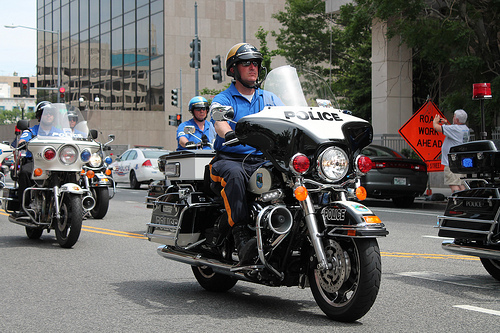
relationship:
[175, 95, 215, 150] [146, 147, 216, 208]
policeman riding motorcycle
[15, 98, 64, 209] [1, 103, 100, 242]
policeman riding motorcycle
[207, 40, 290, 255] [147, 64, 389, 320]
policeman riding motorcycle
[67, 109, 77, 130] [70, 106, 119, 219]
policeman riding motorcycle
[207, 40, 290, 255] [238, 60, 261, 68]
policeman wearing sunglasses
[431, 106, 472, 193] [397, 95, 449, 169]
man working on sign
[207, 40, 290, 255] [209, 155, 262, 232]
policeman wearing pants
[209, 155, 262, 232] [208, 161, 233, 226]
pants have stripe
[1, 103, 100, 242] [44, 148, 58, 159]
motorcycle has light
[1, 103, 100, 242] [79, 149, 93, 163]
motorcycle has light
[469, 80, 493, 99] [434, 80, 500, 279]
light back of motorcycle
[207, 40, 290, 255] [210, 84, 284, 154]
policeman wearing shirt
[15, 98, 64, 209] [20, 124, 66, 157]
policeman wearing shirt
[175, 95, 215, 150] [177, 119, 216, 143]
policeman wearing shirt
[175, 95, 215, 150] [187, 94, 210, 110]
policeman has helmet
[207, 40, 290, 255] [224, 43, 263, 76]
policeman wearing helmet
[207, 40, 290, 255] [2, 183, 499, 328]
policeman riding down road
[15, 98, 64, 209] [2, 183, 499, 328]
policeman riding on road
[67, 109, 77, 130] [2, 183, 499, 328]
policeman riding on road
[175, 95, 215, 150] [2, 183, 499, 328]
policeman riding on road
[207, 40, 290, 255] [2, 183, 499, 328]
policeman patrols road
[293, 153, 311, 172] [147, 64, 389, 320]
light on motorcycle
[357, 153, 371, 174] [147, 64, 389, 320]
light on motorcycle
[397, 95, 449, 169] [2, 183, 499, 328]
sign along road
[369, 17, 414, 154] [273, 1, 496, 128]
pillar front of trees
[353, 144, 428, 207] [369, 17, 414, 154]
car front of pillar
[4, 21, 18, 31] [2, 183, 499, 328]
light over road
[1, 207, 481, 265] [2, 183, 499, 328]
line in road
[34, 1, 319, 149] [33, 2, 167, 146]
building has wall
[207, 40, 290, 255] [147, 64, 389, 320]
policeman on motorcycle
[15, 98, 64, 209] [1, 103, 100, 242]
policeman on motorcycle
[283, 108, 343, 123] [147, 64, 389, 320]
police written on motorcycle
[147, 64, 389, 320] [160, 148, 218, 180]
motorcycle has bin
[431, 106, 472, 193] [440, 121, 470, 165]
man in shirt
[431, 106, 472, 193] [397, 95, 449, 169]
man touching sign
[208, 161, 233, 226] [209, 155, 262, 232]
stripe on pants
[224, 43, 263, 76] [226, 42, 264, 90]
helmet on head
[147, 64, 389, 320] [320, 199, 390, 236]
motorcycle has fender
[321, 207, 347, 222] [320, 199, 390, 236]
word on fender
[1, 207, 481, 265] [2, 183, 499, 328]
line on road